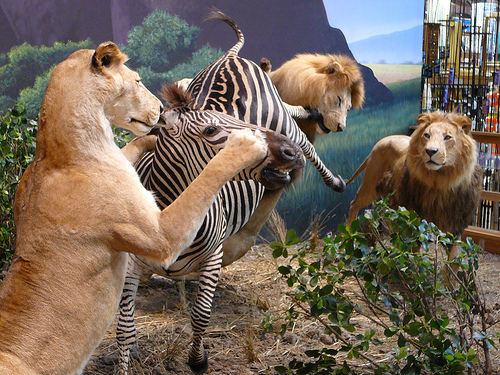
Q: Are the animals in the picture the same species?
A: No, they are lions and zebras.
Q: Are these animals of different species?
A: Yes, they are lions and zebras.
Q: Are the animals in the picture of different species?
A: Yes, they are lions and zebras.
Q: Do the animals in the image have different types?
A: Yes, they are lions and zebras.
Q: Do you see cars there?
A: No, there are no cars.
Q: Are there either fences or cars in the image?
A: No, there are no cars or fences.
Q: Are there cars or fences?
A: No, there are no cars or fences.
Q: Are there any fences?
A: No, there are no fences.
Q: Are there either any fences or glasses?
A: No, there are no fences or glasses.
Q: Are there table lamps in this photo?
A: No, there are no table lamps.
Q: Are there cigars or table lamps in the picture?
A: No, there are no table lamps or cigars.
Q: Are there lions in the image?
A: Yes, there is a lion.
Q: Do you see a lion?
A: Yes, there is a lion.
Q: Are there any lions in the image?
A: Yes, there is a lion.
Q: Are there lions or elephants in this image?
A: Yes, there is a lion.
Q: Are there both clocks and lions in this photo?
A: No, there is a lion but no clocks.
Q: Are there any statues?
A: No, there are no statues.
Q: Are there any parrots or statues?
A: No, there are no statues or parrots.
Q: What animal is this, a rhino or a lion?
A: This is a lion.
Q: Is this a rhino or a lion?
A: This is a lion.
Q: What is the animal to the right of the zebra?
A: The animal is a lion.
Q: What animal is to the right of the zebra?
A: The animal is a lion.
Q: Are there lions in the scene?
A: Yes, there is a lion.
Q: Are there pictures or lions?
A: Yes, there is a lion.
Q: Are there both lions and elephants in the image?
A: No, there is a lion but no elephants.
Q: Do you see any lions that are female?
A: Yes, there is a female lion.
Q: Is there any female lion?
A: Yes, there is a female lion.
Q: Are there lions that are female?
A: Yes, there is a lion that is female.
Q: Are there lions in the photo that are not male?
A: Yes, there is a female lion.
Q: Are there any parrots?
A: No, there are no parrots.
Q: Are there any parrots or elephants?
A: No, there are no parrots or elephants.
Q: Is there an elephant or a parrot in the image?
A: No, there are no parrots or elephants.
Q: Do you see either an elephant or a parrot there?
A: No, there are no parrots or elephants.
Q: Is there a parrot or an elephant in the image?
A: No, there are no parrots or elephants.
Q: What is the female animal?
A: The animal is a lion.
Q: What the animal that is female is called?
A: The animal is a lion.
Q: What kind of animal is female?
A: The animal is a lion.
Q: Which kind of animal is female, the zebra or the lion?
A: The lion is female.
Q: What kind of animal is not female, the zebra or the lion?
A: The zebra is not female.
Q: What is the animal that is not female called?
A: The animal is a zebra.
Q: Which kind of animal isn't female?
A: The animal is a zebra.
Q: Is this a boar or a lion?
A: This is a lion.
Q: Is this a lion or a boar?
A: This is a lion.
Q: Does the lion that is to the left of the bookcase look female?
A: Yes, the lion is female.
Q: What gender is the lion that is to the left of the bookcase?
A: The lion is female.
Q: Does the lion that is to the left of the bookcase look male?
A: No, the lion is female.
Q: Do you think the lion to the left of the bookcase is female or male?
A: The lion is female.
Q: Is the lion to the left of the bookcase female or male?
A: The lion is female.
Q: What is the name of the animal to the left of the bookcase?
A: The animal is a lion.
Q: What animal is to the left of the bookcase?
A: The animal is a lion.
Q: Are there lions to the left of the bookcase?
A: Yes, there is a lion to the left of the bookcase.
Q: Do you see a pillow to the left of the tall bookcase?
A: No, there is a lion to the left of the bookcase.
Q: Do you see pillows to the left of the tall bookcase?
A: No, there is a lion to the left of the bookcase.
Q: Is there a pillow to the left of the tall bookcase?
A: No, there is a lion to the left of the bookcase.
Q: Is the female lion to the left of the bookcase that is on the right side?
A: Yes, the lion is to the left of the bookcase.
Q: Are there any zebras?
A: Yes, there is a zebra.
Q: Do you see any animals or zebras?
A: Yes, there is a zebra.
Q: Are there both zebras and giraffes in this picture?
A: No, there is a zebra but no giraffes.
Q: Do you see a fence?
A: No, there are no fences.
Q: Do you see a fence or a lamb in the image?
A: No, there are no fences or lambs.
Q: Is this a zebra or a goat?
A: This is a zebra.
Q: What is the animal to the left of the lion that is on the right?
A: The animal is a zebra.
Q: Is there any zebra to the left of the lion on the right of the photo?
A: Yes, there is a zebra to the left of the lion.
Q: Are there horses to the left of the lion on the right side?
A: No, there is a zebra to the left of the lion.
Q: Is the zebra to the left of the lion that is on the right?
A: Yes, the zebra is to the left of the lion.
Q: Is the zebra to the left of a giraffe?
A: No, the zebra is to the left of the lion.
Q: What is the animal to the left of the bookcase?
A: The animal is a zebra.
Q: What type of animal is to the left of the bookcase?
A: The animal is a zebra.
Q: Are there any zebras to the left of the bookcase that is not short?
A: Yes, there is a zebra to the left of the bookcase.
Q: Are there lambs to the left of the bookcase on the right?
A: No, there is a zebra to the left of the bookcase.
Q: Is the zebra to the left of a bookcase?
A: Yes, the zebra is to the left of a bookcase.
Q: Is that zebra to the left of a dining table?
A: No, the zebra is to the left of a bookcase.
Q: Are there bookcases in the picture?
A: Yes, there is a bookcase.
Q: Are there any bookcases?
A: Yes, there is a bookcase.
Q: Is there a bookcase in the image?
A: Yes, there is a bookcase.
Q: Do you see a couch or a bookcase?
A: Yes, there is a bookcase.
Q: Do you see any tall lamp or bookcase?
A: Yes, there is a tall bookcase.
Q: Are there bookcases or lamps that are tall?
A: Yes, the bookcase is tall.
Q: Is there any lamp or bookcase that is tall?
A: Yes, the bookcase is tall.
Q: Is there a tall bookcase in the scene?
A: Yes, there is a tall bookcase.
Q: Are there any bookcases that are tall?
A: Yes, there is a bookcase that is tall.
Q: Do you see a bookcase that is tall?
A: Yes, there is a bookcase that is tall.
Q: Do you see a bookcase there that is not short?
A: Yes, there is a tall bookcase.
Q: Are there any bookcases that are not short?
A: Yes, there is a tall bookcase.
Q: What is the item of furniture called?
A: The piece of furniture is a bookcase.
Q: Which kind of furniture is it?
A: The piece of furniture is a bookcase.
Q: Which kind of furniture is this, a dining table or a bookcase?
A: That is a bookcase.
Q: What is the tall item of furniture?
A: The piece of furniture is a bookcase.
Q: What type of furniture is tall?
A: The furniture is a bookcase.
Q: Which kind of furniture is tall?
A: The furniture is a bookcase.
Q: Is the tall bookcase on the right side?
A: Yes, the bookcase is on the right of the image.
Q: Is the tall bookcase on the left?
A: No, the bookcase is on the right of the image.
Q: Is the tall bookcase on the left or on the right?
A: The bookcase is on the right of the image.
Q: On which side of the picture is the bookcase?
A: The bookcase is on the right of the image.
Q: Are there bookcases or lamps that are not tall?
A: No, there is a bookcase but it is tall.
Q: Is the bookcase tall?
A: Yes, the bookcase is tall.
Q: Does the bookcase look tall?
A: Yes, the bookcase is tall.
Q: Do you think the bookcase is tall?
A: Yes, the bookcase is tall.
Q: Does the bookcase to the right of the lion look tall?
A: Yes, the bookcase is tall.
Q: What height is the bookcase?
A: The bookcase is tall.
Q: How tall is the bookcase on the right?
A: The bookcase is tall.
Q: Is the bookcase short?
A: No, the bookcase is tall.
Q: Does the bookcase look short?
A: No, the bookcase is tall.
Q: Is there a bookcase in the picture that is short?
A: No, there is a bookcase but it is tall.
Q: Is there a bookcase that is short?
A: No, there is a bookcase but it is tall.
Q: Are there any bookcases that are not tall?
A: No, there is a bookcase but it is tall.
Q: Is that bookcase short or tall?
A: The bookcase is tall.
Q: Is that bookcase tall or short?
A: The bookcase is tall.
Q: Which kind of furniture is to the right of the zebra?
A: The piece of furniture is a bookcase.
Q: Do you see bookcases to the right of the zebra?
A: Yes, there is a bookcase to the right of the zebra.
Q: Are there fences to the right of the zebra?
A: No, there is a bookcase to the right of the zebra.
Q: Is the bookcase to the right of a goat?
A: No, the bookcase is to the right of the zebra.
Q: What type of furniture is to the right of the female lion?
A: The piece of furniture is a bookcase.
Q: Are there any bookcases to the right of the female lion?
A: Yes, there is a bookcase to the right of the lion.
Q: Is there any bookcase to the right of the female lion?
A: Yes, there is a bookcase to the right of the lion.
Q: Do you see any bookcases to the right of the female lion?
A: Yes, there is a bookcase to the right of the lion.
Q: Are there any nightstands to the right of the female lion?
A: No, there is a bookcase to the right of the lion.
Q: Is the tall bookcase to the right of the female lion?
A: Yes, the bookcase is to the right of the lion.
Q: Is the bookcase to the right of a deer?
A: No, the bookcase is to the right of the lion.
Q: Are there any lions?
A: Yes, there is a lion.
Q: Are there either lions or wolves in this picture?
A: Yes, there is a lion.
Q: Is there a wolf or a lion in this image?
A: Yes, there is a lion.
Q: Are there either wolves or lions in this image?
A: Yes, there is a lion.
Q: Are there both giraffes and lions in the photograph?
A: No, there is a lion but no giraffes.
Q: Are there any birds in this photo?
A: No, there are no birds.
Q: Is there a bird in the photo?
A: No, there are no birds.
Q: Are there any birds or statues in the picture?
A: No, there are no birds or statues.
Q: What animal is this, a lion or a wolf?
A: This is a lion.